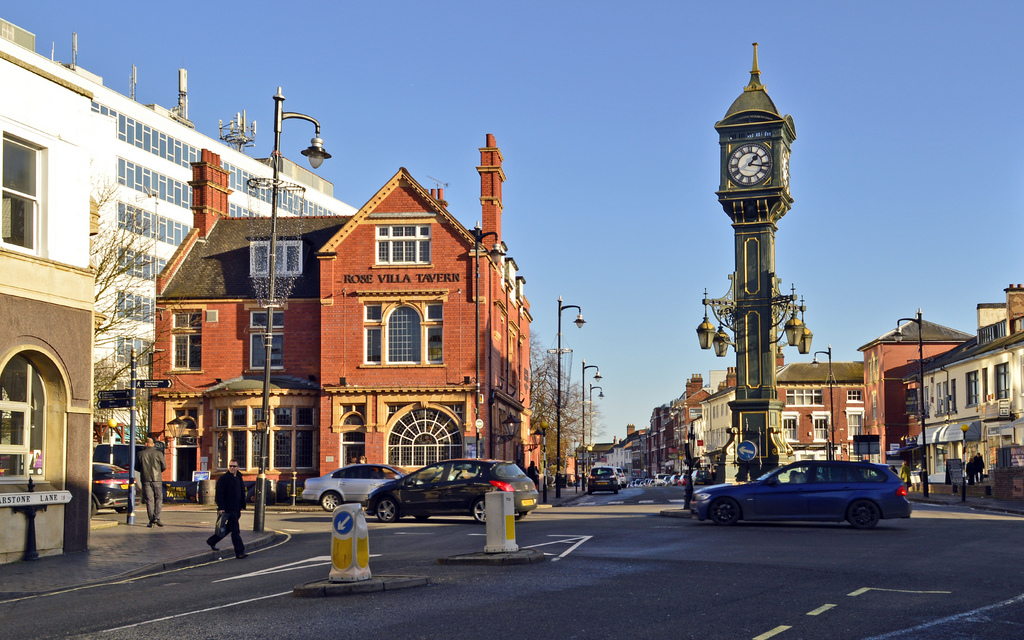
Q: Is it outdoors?
A: Yes, it is outdoors.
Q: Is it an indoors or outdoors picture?
A: It is outdoors.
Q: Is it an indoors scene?
A: No, it is outdoors.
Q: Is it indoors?
A: No, it is outdoors.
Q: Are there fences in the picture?
A: No, there are no fences.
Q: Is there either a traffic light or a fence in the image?
A: No, there are no fences or traffic lights.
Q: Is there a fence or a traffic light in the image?
A: No, there are no fences or traffic lights.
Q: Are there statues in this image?
A: No, there are no statues.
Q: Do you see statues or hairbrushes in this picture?
A: No, there are no statues or hairbrushes.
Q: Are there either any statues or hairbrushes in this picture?
A: No, there are no statues or hairbrushes.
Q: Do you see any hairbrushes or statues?
A: No, there are no statues or hairbrushes.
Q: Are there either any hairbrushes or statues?
A: No, there are no statues or hairbrushes.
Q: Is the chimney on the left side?
A: Yes, the chimney is on the left of the image.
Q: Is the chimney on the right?
A: No, the chimney is on the left of the image.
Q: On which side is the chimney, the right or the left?
A: The chimney is on the left of the image.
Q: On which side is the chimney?
A: The chimney is on the left of the image.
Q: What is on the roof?
A: The chimney is on the roof.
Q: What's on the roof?
A: The chimney is on the roof.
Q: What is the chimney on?
A: The chimney is on the roof.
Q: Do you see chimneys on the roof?
A: Yes, there is a chimney on the roof.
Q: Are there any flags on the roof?
A: No, there is a chimney on the roof.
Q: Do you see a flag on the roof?
A: No, there is a chimney on the roof.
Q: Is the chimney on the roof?
A: Yes, the chimney is on the roof.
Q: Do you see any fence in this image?
A: No, there are no fences.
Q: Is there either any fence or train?
A: No, there are no fences or trains.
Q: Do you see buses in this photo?
A: No, there are no buses.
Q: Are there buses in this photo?
A: No, there are no buses.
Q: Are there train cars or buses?
A: No, there are no buses or train cars.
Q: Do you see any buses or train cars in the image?
A: No, there are no buses or train cars.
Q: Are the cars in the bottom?
A: Yes, the cars are in the bottom of the image.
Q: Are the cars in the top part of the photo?
A: No, the cars are in the bottom of the image.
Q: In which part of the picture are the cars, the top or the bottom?
A: The cars are in the bottom of the image.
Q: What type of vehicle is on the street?
A: The vehicles are cars.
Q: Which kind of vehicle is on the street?
A: The vehicles are cars.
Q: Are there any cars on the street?
A: Yes, there are cars on the street.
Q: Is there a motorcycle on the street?
A: No, there are cars on the street.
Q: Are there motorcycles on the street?
A: No, there are cars on the street.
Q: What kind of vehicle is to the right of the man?
A: The vehicles are cars.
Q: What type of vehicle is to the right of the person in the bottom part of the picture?
A: The vehicles are cars.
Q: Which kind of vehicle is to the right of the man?
A: The vehicles are cars.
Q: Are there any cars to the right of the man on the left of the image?
A: Yes, there are cars to the right of the man.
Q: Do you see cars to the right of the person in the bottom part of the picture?
A: Yes, there are cars to the right of the man.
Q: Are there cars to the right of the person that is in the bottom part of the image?
A: Yes, there are cars to the right of the man.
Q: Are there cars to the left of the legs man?
A: No, the cars are to the right of the man.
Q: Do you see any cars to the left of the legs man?
A: No, the cars are to the right of the man.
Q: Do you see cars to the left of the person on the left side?
A: No, the cars are to the right of the man.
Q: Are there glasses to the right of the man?
A: No, there are cars to the right of the man.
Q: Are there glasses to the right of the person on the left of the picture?
A: No, there are cars to the right of the man.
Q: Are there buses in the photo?
A: No, there are no buses.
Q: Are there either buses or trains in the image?
A: No, there are no buses or trains.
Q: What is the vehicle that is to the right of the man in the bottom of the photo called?
A: The vehicle is a car.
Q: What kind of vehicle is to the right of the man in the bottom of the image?
A: The vehicle is a car.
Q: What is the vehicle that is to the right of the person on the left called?
A: The vehicle is a car.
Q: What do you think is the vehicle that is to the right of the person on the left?
A: The vehicle is a car.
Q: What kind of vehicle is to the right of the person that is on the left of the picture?
A: The vehicle is a car.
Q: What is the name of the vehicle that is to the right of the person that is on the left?
A: The vehicle is a car.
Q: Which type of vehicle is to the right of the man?
A: The vehicle is a car.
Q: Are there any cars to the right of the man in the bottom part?
A: Yes, there is a car to the right of the man.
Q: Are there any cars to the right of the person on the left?
A: Yes, there is a car to the right of the man.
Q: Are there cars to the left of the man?
A: No, the car is to the right of the man.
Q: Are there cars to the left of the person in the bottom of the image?
A: No, the car is to the right of the man.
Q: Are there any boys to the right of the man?
A: No, there is a car to the right of the man.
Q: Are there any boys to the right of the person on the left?
A: No, there is a car to the right of the man.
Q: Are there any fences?
A: No, there are no fences.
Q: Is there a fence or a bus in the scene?
A: No, there are no fences or buses.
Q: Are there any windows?
A: Yes, there are windows.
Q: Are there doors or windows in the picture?
A: Yes, there are windows.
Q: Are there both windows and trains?
A: No, there are windows but no trains.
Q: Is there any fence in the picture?
A: No, there are no fences.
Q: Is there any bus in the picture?
A: No, there are no buses.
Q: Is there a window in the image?
A: Yes, there are windows.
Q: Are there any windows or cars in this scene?
A: Yes, there are windows.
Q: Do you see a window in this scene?
A: Yes, there is a window.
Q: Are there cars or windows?
A: Yes, there is a window.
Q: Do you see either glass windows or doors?
A: Yes, there is a glass window.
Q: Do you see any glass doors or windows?
A: Yes, there is a glass window.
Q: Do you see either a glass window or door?
A: Yes, there is a glass window.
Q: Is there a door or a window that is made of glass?
A: Yes, the window is made of glass.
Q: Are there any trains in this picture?
A: No, there are no trains.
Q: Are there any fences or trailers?
A: No, there are no fences or trailers.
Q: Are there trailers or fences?
A: No, there are no fences or trailers.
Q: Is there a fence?
A: No, there are no fences.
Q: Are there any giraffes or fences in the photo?
A: No, there are no fences or giraffes.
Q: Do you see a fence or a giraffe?
A: No, there are no fences or giraffes.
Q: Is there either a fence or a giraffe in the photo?
A: No, there are no fences or giraffes.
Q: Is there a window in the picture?
A: Yes, there is a window.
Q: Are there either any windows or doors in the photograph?
A: Yes, there is a window.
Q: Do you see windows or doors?
A: Yes, there is a window.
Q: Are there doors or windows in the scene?
A: Yes, there is a window.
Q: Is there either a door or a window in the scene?
A: Yes, there is a window.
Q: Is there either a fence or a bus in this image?
A: No, there are no fences or buses.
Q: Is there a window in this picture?
A: Yes, there is a window.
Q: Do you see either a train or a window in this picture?
A: Yes, there is a window.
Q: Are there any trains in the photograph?
A: No, there are no trains.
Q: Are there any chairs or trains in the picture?
A: No, there are no trains or chairs.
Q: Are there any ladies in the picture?
A: No, there are no ladies.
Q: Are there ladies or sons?
A: No, there are no ladies or sons.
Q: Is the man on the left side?
A: Yes, the man is on the left of the image.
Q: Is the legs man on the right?
A: No, the man is on the left of the image.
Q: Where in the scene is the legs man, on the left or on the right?
A: The man is on the left of the image.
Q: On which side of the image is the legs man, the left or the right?
A: The man is on the left of the image.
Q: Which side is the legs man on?
A: The man is on the left of the image.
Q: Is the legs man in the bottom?
A: Yes, the man is in the bottom of the image.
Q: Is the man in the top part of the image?
A: No, the man is in the bottom of the image.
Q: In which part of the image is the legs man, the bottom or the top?
A: The man is in the bottom of the image.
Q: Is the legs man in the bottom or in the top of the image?
A: The man is in the bottom of the image.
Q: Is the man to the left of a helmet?
A: No, the man is to the left of the car.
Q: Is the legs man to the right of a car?
A: No, the man is to the left of a car.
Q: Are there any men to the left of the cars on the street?
A: Yes, there is a man to the left of the cars.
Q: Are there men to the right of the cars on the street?
A: No, the man is to the left of the cars.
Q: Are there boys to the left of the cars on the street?
A: No, there is a man to the left of the cars.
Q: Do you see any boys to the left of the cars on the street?
A: No, there is a man to the left of the cars.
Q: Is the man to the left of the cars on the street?
A: Yes, the man is to the left of the cars.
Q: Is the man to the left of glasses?
A: No, the man is to the left of the cars.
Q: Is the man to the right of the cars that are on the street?
A: No, the man is to the left of the cars.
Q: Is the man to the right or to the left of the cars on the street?
A: The man is to the left of the cars.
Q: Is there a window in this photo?
A: Yes, there is a window.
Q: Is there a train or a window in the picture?
A: Yes, there is a window.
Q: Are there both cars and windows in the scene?
A: Yes, there are both a window and a car.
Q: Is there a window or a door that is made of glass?
A: Yes, the window is made of glass.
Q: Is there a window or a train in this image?
A: Yes, there is a window.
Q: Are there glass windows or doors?
A: Yes, there is a glass window.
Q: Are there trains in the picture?
A: No, there are no trains.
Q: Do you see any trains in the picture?
A: No, there are no trains.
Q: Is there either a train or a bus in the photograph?
A: No, there are no trains or buses.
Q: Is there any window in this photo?
A: Yes, there is a window.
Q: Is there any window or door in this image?
A: Yes, there is a window.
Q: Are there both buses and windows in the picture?
A: No, there is a window but no buses.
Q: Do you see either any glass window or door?
A: Yes, there is a glass window.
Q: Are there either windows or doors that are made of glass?
A: Yes, the window is made of glass.